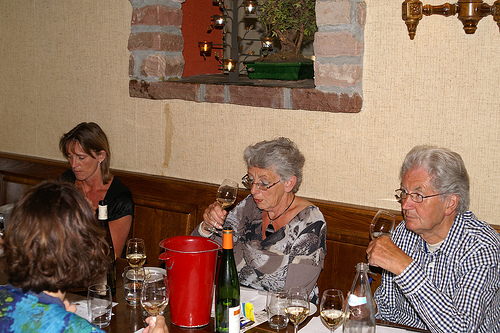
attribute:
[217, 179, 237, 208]
wine glass — clear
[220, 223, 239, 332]
bottle — green, glass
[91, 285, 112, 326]
glass — clear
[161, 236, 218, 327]
bucket — red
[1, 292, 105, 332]
woman's shirt — green, blue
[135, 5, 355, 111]
brick hole — red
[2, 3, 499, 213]
wall — brown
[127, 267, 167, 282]
plate — white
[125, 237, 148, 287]
glass — brown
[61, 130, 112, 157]
woman's hair — brown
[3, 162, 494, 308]
bench — wooden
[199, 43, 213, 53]
candle — lit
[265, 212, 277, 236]
necklace — black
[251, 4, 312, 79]
plant — green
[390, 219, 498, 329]
man's shirt — checkered, blue black white, black, white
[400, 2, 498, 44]
light fixture — wooden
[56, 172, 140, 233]
woman's shirt — black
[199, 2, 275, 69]
candles — black